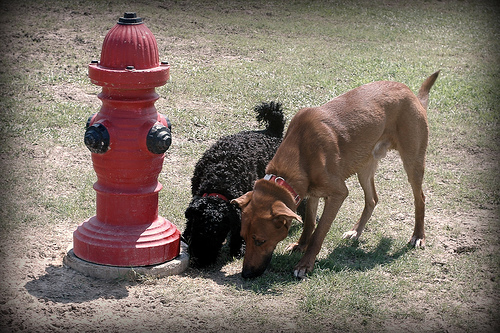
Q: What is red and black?
A: Water hydrant.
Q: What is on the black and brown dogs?
A: Red collar.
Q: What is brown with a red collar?
A: A dog.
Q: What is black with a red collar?
A: A dog.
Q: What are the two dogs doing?
A: Sniffing the ground.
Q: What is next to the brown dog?
A: A black dog.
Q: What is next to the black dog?
A: A brown dog.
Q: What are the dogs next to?
A: Red fire hydrant.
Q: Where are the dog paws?
A: On the ground.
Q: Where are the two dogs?
A: Next to a fire hydrant.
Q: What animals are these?
A: Dogs.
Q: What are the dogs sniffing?
A: Grass.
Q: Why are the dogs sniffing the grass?
A: Detect scent.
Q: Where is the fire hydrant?
A: In a field.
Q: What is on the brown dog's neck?
A: Collar.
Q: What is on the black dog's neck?
A: Collar.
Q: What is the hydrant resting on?
A: Concrete slab.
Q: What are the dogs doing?
A: Sniffing.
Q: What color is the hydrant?
A: Red.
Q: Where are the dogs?
A: By the hydrant.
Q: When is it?
A: Daytime.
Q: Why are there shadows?
A: It is sunny.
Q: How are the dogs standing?
A: Side by side.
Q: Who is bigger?
A: The brown dog.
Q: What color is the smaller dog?
A: Black.